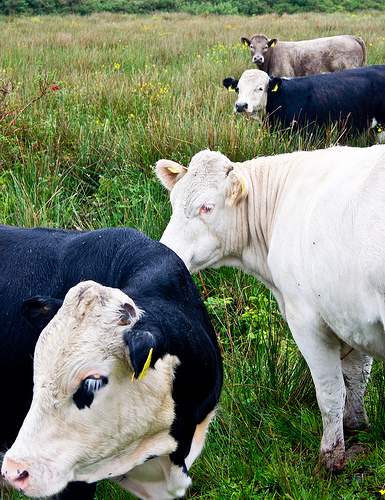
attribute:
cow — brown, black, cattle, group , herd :
[240, 30, 369, 69]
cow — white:
[173, 149, 383, 428]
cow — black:
[229, 69, 384, 135]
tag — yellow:
[136, 345, 161, 380]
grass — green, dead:
[4, 13, 383, 499]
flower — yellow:
[105, 42, 249, 140]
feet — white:
[317, 425, 369, 473]